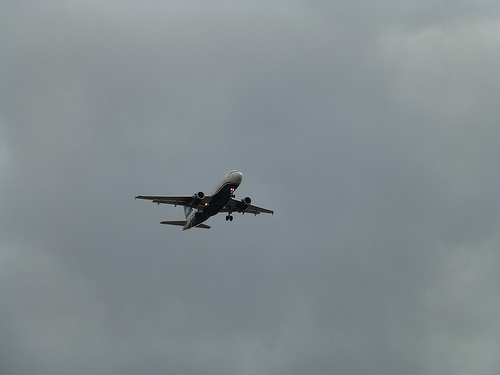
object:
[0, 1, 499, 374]
cloudy sky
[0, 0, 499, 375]
clouds